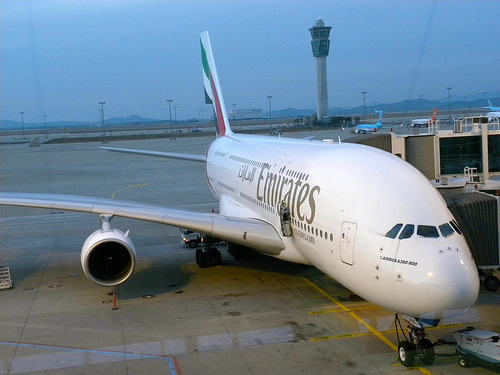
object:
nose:
[421, 252, 479, 315]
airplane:
[0, 31, 480, 371]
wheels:
[400, 339, 435, 366]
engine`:
[82, 229, 137, 288]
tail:
[199, 31, 233, 137]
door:
[339, 221, 358, 267]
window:
[329, 233, 334, 242]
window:
[319, 230, 323, 238]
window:
[308, 225, 311, 232]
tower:
[309, 19, 333, 125]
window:
[416, 225, 440, 239]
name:
[257, 164, 323, 225]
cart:
[438, 134, 483, 176]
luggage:
[440, 140, 480, 172]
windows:
[385, 223, 403, 240]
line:
[414, 360, 430, 373]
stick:
[430, 106, 439, 131]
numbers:
[382, 256, 417, 266]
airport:
[0, 107, 499, 374]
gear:
[394, 315, 434, 365]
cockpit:
[377, 205, 466, 254]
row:
[213, 151, 312, 182]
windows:
[280, 165, 287, 174]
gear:
[195, 235, 221, 268]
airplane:
[354, 110, 383, 134]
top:
[314, 18, 324, 26]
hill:
[330, 98, 500, 116]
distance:
[1, 0, 498, 129]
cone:
[211, 206, 216, 213]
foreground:
[4, 120, 499, 374]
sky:
[2, 0, 496, 121]